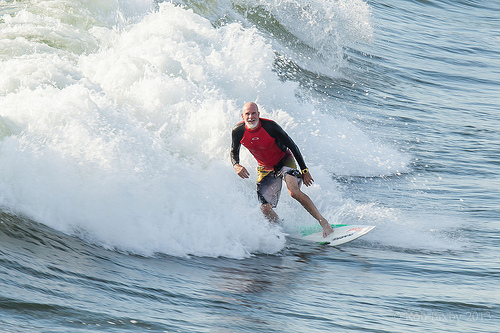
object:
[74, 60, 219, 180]
spray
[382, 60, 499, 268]
water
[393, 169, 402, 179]
water droplets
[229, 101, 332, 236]
man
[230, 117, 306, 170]
shirt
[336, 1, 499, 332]
ocean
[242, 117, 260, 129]
beard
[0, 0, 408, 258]
wave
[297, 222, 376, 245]
board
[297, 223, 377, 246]
surfboard